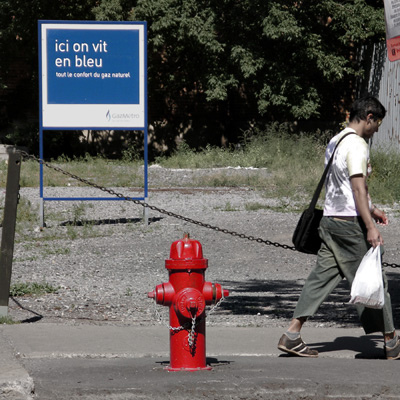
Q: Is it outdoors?
A: Yes, it is outdoors.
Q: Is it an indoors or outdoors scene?
A: It is outdoors.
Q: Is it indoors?
A: No, it is outdoors.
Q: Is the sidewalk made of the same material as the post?
A: No, the sidewalk is made of concrete and the post is made of metal.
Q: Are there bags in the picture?
A: Yes, there is a bag.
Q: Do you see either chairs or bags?
A: Yes, there is a bag.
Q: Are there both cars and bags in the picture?
A: No, there is a bag but no cars.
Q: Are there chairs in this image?
A: No, there are no chairs.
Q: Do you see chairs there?
A: No, there are no chairs.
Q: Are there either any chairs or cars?
A: No, there are no chairs or cars.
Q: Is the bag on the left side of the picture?
A: No, the bag is on the right of the image.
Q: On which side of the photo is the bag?
A: The bag is on the right of the image.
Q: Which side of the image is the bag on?
A: The bag is on the right of the image.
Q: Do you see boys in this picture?
A: No, there are no boys.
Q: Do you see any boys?
A: No, there are no boys.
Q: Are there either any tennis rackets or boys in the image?
A: No, there are no boys or tennis rackets.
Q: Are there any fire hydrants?
A: Yes, there is a fire hydrant.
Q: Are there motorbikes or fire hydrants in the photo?
A: Yes, there is a fire hydrant.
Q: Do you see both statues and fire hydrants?
A: No, there is a fire hydrant but no statues.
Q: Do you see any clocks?
A: No, there are no clocks.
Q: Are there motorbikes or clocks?
A: No, there are no clocks or motorbikes.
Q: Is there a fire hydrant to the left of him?
A: Yes, there is a fire hydrant to the left of the man.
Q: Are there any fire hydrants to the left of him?
A: Yes, there is a fire hydrant to the left of the man.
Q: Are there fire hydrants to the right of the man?
A: No, the fire hydrant is to the left of the man.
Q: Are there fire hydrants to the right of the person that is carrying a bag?
A: No, the fire hydrant is to the left of the man.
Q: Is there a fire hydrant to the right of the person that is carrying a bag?
A: No, the fire hydrant is to the left of the man.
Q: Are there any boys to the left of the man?
A: No, there is a fire hydrant to the left of the man.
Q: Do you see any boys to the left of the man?
A: No, there is a fire hydrant to the left of the man.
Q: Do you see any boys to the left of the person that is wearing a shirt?
A: No, there is a fire hydrant to the left of the man.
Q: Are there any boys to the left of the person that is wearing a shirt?
A: No, there is a fire hydrant to the left of the man.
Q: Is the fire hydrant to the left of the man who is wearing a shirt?
A: Yes, the fire hydrant is to the left of the man.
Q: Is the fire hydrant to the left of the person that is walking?
A: Yes, the fire hydrant is to the left of the man.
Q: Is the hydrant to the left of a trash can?
A: No, the hydrant is to the left of the man.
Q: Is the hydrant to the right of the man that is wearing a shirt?
A: No, the hydrant is to the left of the man.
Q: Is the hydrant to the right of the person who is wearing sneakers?
A: No, the hydrant is to the left of the man.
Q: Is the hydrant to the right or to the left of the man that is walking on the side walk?
A: The hydrant is to the left of the man.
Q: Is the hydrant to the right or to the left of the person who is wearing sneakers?
A: The hydrant is to the left of the man.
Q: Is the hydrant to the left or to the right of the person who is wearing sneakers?
A: The hydrant is to the left of the man.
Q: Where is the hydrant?
A: The hydrant is on the street.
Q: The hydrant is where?
A: The hydrant is on the street.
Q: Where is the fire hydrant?
A: The hydrant is on the street.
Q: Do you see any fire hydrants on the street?
A: Yes, there is a fire hydrant on the street.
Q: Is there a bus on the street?
A: No, there is a fire hydrant on the street.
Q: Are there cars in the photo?
A: No, there are no cars.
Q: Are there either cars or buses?
A: No, there are no cars or buses.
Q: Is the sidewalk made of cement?
A: Yes, the sidewalk is made of cement.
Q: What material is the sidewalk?
A: The sidewalk is made of cement.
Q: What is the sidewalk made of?
A: The sidewalk is made of concrete.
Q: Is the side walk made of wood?
A: No, the side walk is made of cement.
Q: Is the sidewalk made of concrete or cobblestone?
A: The sidewalk is made of concrete.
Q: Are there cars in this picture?
A: No, there are no cars.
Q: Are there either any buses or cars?
A: No, there are no cars or buses.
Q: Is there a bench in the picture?
A: No, there are no benches.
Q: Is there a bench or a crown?
A: No, there are no benches or crowns.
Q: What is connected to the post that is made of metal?
A: The chain is connected to the post.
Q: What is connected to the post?
A: The chain is connected to the post.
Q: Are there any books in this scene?
A: No, there are no books.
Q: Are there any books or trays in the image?
A: No, there are no books or trays.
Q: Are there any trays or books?
A: No, there are no books or trays.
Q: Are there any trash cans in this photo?
A: No, there are no trash cans.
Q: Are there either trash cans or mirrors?
A: No, there are no trash cans or mirrors.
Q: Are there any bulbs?
A: No, there are no bulbs.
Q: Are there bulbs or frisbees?
A: No, there are no bulbs or frisbees.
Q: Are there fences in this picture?
A: Yes, there is a fence.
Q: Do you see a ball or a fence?
A: Yes, there is a fence.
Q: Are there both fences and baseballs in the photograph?
A: No, there is a fence but no baseballs.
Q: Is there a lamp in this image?
A: No, there are no lamps.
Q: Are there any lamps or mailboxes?
A: No, there are no lamps or mailboxes.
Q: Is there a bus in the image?
A: No, there are no buses.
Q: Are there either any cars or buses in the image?
A: No, there are no buses or cars.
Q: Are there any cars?
A: No, there are no cars.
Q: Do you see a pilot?
A: No, there are no pilots.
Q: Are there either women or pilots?
A: No, there are no pilots or women.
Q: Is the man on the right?
A: Yes, the man is on the right of the image.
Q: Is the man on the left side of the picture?
A: No, the man is on the right of the image.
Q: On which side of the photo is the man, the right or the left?
A: The man is on the right of the image.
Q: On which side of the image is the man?
A: The man is on the right of the image.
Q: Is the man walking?
A: Yes, the man is walking.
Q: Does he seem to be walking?
A: Yes, the man is walking.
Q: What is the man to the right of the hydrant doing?
A: The man is walking.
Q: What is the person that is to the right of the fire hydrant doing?
A: The man is walking.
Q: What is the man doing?
A: The man is walking.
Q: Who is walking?
A: The man is walking.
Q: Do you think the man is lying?
A: No, the man is walking.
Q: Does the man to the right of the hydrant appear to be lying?
A: No, the man is walking.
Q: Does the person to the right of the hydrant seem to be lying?
A: No, the man is walking.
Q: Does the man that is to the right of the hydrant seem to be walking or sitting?
A: The man is walking.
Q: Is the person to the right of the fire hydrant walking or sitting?
A: The man is walking.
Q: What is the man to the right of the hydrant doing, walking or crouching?
A: The man is walking.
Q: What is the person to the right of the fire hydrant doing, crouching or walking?
A: The man is walking.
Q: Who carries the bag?
A: The man carries the bag.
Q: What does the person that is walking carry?
A: The man carries a bag.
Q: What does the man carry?
A: The man carries a bag.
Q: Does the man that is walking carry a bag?
A: Yes, the man carries a bag.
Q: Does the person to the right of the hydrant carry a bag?
A: Yes, the man carries a bag.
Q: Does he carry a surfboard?
A: No, the man carries a bag.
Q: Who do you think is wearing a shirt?
A: The man is wearing a shirt.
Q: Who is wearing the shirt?
A: The man is wearing a shirt.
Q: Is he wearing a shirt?
A: Yes, the man is wearing a shirt.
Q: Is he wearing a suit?
A: No, the man is wearing a shirt.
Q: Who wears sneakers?
A: The man wears sneakers.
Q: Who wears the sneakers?
A: The man wears sneakers.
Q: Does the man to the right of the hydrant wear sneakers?
A: Yes, the man wears sneakers.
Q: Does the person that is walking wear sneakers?
A: Yes, the man wears sneakers.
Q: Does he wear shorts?
A: No, the man wears sneakers.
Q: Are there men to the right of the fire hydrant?
A: Yes, there is a man to the right of the fire hydrant.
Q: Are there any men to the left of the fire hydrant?
A: No, the man is to the right of the fire hydrant.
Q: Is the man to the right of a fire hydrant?
A: Yes, the man is to the right of a fire hydrant.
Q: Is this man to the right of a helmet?
A: No, the man is to the right of a fire hydrant.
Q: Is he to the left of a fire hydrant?
A: No, the man is to the right of a fire hydrant.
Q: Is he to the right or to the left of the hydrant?
A: The man is to the right of the hydrant.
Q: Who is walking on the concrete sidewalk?
A: The man is walking on the side walk.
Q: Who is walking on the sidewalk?
A: The man is walking on the side walk.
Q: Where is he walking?
A: The man is walking on the sidewalk.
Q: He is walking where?
A: The man is walking on the sidewalk.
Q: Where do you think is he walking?
A: The man is walking on the sidewalk.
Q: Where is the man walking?
A: The man is walking on the sidewalk.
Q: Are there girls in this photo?
A: No, there are no girls.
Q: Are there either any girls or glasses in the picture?
A: No, there are no girls or glasses.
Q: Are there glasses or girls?
A: No, there are no girls or glasses.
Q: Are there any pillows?
A: No, there are no pillows.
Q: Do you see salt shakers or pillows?
A: No, there are no pillows or salt shakers.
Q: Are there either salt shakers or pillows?
A: No, there are no pillows or salt shakers.